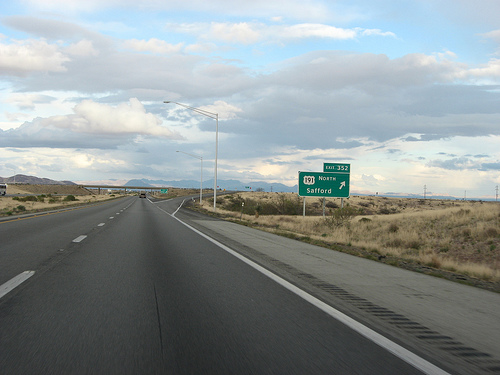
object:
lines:
[120, 210, 123, 212]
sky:
[0, 0, 500, 198]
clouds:
[0, 0, 500, 199]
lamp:
[175, 150, 201, 203]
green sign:
[298, 171, 350, 197]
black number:
[305, 177, 308, 182]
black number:
[308, 177, 311, 183]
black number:
[312, 178, 314, 183]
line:
[98, 223, 106, 227]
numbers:
[341, 166, 344, 170]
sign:
[323, 162, 351, 174]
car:
[138, 190, 146, 199]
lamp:
[162, 100, 217, 210]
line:
[171, 215, 450, 374]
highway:
[1, 192, 498, 373]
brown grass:
[184, 190, 498, 280]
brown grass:
[0, 174, 137, 212]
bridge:
[76, 185, 187, 195]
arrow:
[339, 181, 345, 190]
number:
[337, 166, 340, 170]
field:
[181, 192, 500, 291]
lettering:
[307, 187, 331, 193]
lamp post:
[163, 101, 218, 212]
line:
[115, 212, 119, 214]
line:
[109, 217, 114, 219]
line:
[72, 234, 87, 243]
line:
[0, 269, 34, 297]